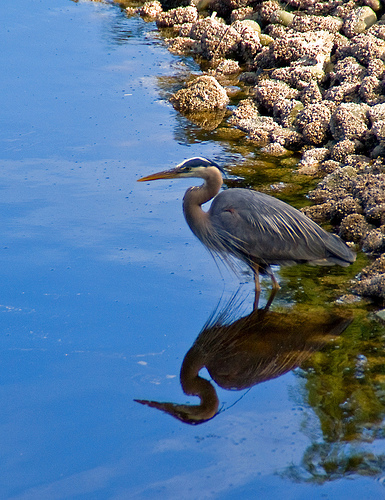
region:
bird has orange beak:
[145, 158, 169, 195]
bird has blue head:
[157, 163, 213, 181]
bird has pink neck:
[198, 164, 213, 204]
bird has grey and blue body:
[198, 190, 281, 261]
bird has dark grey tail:
[301, 232, 359, 277]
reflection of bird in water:
[145, 272, 328, 430]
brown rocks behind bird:
[222, 8, 368, 177]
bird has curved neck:
[180, 188, 226, 226]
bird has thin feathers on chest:
[205, 235, 241, 313]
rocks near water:
[152, 50, 273, 210]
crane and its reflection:
[119, 145, 370, 466]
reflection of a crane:
[124, 296, 327, 453]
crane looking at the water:
[110, 138, 380, 309]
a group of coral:
[215, 18, 367, 162]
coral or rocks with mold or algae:
[230, 57, 363, 170]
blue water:
[18, 252, 109, 397]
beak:
[128, 159, 181, 193]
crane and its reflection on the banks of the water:
[17, 43, 361, 488]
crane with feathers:
[102, 136, 367, 299]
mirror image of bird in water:
[115, 294, 383, 447]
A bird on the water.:
[125, 154, 358, 320]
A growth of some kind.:
[166, 76, 225, 109]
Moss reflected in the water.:
[304, 373, 383, 430]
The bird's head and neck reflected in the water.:
[121, 385, 227, 435]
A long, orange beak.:
[134, 172, 184, 183]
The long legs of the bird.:
[248, 261, 279, 322]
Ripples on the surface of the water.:
[47, 22, 159, 70]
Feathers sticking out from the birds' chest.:
[197, 224, 252, 286]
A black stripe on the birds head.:
[179, 159, 220, 170]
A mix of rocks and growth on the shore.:
[122, 3, 383, 135]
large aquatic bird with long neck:
[122, 145, 359, 316]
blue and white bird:
[126, 150, 383, 315]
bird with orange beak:
[126, 140, 358, 325]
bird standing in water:
[125, 147, 358, 319]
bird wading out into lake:
[122, 139, 362, 312]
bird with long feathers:
[128, 147, 367, 313]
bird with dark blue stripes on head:
[131, 143, 363, 308]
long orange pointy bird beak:
[132, 157, 177, 187]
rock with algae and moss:
[159, 67, 237, 134]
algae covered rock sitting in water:
[162, 72, 232, 117]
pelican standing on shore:
[139, 137, 348, 322]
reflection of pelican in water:
[118, 308, 328, 432]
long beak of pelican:
[128, 166, 181, 188]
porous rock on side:
[168, 75, 229, 115]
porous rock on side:
[290, 101, 322, 147]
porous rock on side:
[329, 111, 361, 139]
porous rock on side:
[259, 139, 285, 153]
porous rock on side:
[271, 33, 324, 58]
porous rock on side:
[231, 28, 267, 61]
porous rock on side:
[192, 15, 220, 40]